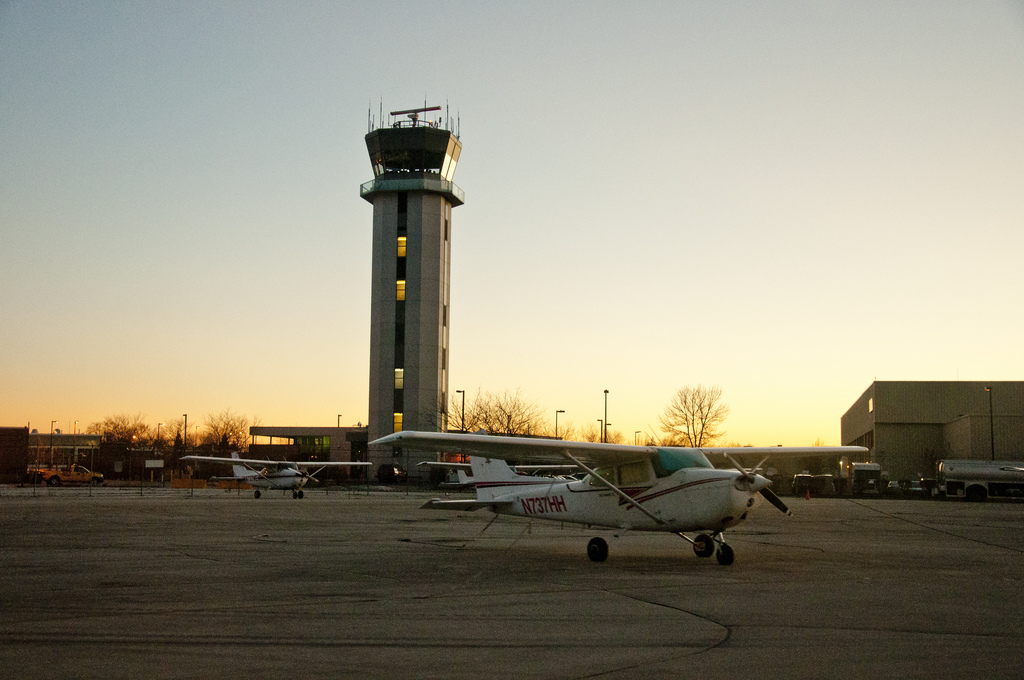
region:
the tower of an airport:
[332, 90, 475, 501]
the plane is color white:
[367, 401, 887, 592]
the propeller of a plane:
[720, 441, 800, 536]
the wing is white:
[702, 429, 874, 484]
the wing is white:
[362, 419, 650, 480]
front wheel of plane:
[685, 520, 743, 572]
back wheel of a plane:
[575, 523, 620, 568]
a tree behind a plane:
[650, 372, 733, 471]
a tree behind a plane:
[445, 384, 563, 442]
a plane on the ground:
[151, 429, 379, 502]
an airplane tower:
[362, 116, 446, 490]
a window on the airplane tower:
[394, 239, 408, 255]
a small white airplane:
[366, 433, 790, 563]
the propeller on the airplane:
[720, 442, 797, 519]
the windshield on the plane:
[656, 448, 718, 471]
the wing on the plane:
[367, 430, 656, 487]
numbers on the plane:
[512, 495, 571, 516]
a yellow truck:
[43, 467, 107, 486]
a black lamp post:
[451, 386, 470, 426]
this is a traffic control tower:
[327, 73, 495, 494]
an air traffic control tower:
[333, 50, 521, 542]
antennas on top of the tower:
[351, 69, 485, 131]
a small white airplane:
[355, 424, 891, 587]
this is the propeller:
[712, 420, 827, 544]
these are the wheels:
[561, 505, 749, 581]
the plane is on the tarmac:
[311, 394, 941, 588]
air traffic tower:
[310, 96, 472, 419]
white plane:
[372, 377, 772, 571]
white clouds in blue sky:
[569, 82, 627, 134]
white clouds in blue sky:
[98, 178, 140, 195]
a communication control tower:
[343, 99, 481, 496]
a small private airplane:
[377, 393, 874, 583]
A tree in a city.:
[657, 384, 734, 446]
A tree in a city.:
[467, 399, 548, 437]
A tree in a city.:
[204, 408, 255, 446]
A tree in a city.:
[167, 412, 186, 444]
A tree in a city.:
[145, 430, 161, 446]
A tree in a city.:
[101, 415, 144, 451]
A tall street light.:
[603, 377, 614, 448]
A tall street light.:
[550, 403, 561, 454]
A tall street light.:
[455, 384, 472, 420]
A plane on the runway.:
[423, 410, 816, 582]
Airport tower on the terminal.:
[351, 95, 488, 383]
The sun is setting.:
[84, 348, 688, 456]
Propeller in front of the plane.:
[717, 442, 795, 516]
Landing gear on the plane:
[678, 512, 765, 563]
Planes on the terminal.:
[179, 430, 769, 548]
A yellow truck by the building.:
[32, 455, 124, 497]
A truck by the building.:
[931, 442, 1023, 513]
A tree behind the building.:
[640, 380, 746, 453]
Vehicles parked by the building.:
[762, 437, 939, 502]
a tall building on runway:
[340, 75, 506, 472]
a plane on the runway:
[354, 407, 808, 586]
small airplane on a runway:
[367, 421, 873, 568]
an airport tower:
[346, 92, 464, 434]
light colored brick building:
[830, 372, 1020, 477]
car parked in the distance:
[20, 454, 109, 492]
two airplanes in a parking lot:
[169, 418, 872, 574]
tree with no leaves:
[649, 377, 732, 447]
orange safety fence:
[153, 465, 255, 500]